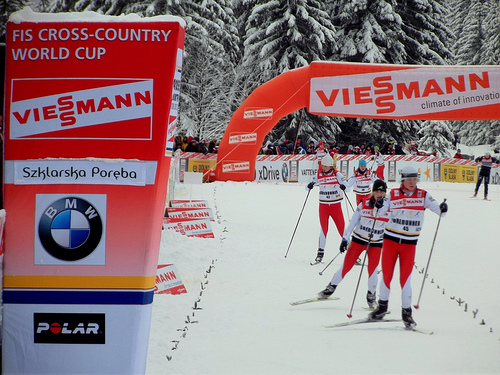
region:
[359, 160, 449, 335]
a cross country skier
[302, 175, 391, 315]
a cross country skier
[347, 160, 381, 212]
a cross country skier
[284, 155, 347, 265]
a cross country skier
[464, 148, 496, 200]
a cross country skier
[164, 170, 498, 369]
a skiing snow path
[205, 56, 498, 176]
an inflatable promotional sign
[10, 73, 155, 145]
a promotional business advertisement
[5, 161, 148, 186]
a promotional business advertisement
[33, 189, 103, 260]
a promotional business advertisement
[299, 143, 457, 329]
snow skiers in a race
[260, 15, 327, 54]
snow cover tree brances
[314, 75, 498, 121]
a white signe with orange writing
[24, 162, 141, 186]
black lettering on a sign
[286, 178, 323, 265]
a ski pole held by a hand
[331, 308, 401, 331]
snow skis on the snow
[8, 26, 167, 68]
white lettering on an orange sign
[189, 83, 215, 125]
snow covered tree branches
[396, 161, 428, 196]
a head of a person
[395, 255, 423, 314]
a leg of a person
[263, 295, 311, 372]
the snow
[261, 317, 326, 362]
the snow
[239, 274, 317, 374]
the snow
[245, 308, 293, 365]
the snow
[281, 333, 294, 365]
the snow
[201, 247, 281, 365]
the snow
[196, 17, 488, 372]
Four skiers in a race.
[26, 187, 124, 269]
Logo for BMW.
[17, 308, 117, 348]
The word POLAR in white and red letters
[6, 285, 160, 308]
A blue stripe on a sign.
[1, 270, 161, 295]
A yellow stripe on a sign.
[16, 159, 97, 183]
The word Szklarska in black letters.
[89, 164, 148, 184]
The word Poreba in black letters.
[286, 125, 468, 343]
Skiers dressed in same uniforms.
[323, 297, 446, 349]
Pair of skis on first skier.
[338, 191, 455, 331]
Ski poles for first skier.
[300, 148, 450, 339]
cross-country skiiers in a race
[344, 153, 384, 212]
skiier has a blue-green cap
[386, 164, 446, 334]
cross-country skiier has a white cap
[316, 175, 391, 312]
cross-country skiier has a black cap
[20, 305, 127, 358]
Polar is a sponsor of this cross-country ski race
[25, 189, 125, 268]
BMW is a sponsor of this cross-country ski race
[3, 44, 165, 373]
advertisers for a World Cup cross country ski race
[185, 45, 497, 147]
snow on the trees at a cross-country ski race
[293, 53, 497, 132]
Viessmann is a sponsor of this cross-country ski race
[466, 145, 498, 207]
spectator skiier at a cross-country ski race